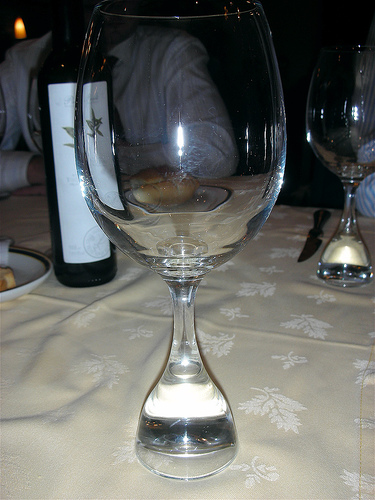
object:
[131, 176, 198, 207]
roll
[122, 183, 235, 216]
plate